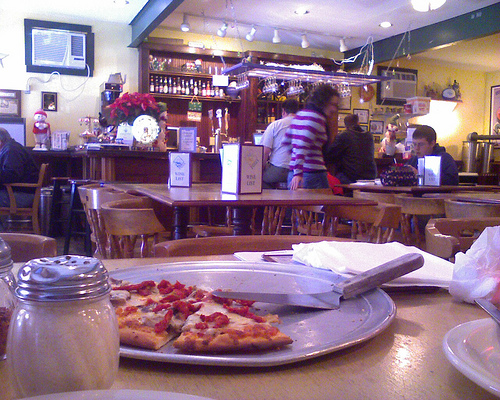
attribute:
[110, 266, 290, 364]
pizza — sliced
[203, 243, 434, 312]
spatula — metal, wood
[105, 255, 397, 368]
pizza pan — silver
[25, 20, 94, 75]
air conditioning — white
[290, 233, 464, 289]
napkins — white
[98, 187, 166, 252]
chair — wooden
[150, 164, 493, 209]
tables — wooden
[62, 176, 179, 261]
chairs — wooden